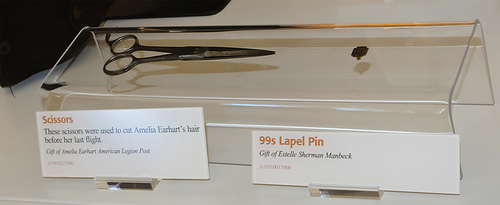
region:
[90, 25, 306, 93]
Pair of steel scissors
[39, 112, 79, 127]
This is a word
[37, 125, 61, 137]
This is a word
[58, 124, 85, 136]
This is a word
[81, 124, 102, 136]
This is a word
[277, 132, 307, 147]
This is a word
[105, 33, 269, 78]
A pair of scissors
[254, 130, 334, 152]
The words 99s Lapel Pin on white background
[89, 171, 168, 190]
A clear lucite card holder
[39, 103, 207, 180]
A small information card for SCISSORS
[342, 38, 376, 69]
A black speck mark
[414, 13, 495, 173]
The edge of a rounded lucite box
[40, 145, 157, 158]
A sentence written in italics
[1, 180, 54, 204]
The edge of a white table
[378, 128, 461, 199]
A blank white card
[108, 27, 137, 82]
Two circular scissor holders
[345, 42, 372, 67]
lapel pin resting on clear plastic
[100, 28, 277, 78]
scissors laying on clear plastic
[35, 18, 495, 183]
clear plastic display bar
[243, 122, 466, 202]
informational identification paper tag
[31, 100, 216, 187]
white paper informational tag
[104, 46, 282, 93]
reflection of scissors in plastic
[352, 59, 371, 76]
reflection on pin in plastic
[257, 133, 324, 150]
99s Lapel Pin written in orange letters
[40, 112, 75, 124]
Scissors written in orange letters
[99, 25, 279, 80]
tarnished scissors laying on display stand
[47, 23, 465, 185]
this is a stand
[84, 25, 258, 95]
these are scissors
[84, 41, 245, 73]
the shears are metal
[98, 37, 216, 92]
the shears are black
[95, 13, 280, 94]
the shears on on display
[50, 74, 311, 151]
the display is glass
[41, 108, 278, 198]
the signs are paper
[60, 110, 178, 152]
the text is black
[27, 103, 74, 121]
the text is orange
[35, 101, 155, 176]
the paper is white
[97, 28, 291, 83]
old scissors on display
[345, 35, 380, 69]
a small pin on display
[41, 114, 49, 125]
orange letter on sign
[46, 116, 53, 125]
orange letter on sign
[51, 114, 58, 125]
orange letter on sign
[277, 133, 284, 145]
orange letter on sign